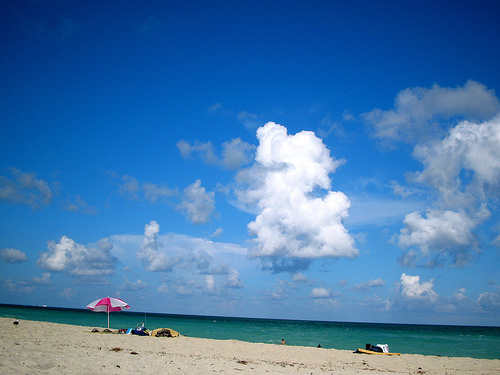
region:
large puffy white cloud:
[206, 75, 381, 278]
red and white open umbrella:
[61, 270, 166, 351]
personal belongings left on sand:
[116, 306, 201, 348]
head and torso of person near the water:
[255, 315, 301, 351]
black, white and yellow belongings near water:
[346, 320, 402, 360]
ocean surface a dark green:
[66, 297, 476, 357]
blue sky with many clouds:
[56, 76, 476, 281]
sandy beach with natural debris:
[35, 102, 445, 282]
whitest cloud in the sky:
[135, 85, 436, 280]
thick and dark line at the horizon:
[46, 297, 487, 344]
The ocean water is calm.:
[0, 297, 498, 367]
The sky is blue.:
[0, 0, 498, 117]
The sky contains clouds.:
[185, 111, 468, 279]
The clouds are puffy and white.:
[221, 111, 385, 286]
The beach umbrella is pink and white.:
[71, 288, 135, 338]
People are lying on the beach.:
[350, 337, 414, 361]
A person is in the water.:
[267, 330, 292, 350]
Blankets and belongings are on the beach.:
[87, 314, 191, 344]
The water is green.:
[0, 294, 497, 361]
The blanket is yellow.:
[350, 345, 407, 360]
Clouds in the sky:
[238, 111, 359, 273]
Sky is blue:
[1, 8, 498, 298]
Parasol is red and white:
[83, 286, 132, 336]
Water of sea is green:
[1, 291, 499, 338]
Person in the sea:
[272, 331, 296, 351]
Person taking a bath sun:
[128, 319, 157, 343]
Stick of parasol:
[102, 306, 114, 331]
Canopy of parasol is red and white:
[74, 294, 133, 318]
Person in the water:
[313, 339, 324, 352]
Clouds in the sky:
[35, 229, 118, 279]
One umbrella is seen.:
[85, 290, 135, 307]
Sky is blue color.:
[35, 125, 175, 195]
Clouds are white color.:
[270, 145, 310, 255]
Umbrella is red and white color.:
[85, 290, 115, 315]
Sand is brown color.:
[10, 331, 90, 361]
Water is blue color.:
[210, 311, 285, 331]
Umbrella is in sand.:
[70, 280, 120, 315]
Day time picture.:
[25, 40, 471, 365]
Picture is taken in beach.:
[25, 56, 482, 371]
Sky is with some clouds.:
[35, 42, 465, 305]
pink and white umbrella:
[86, 294, 128, 324]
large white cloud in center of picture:
[246, 118, 358, 268]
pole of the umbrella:
[104, 303, 114, 330]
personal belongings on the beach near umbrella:
[88, 320, 176, 336]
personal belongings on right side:
[354, 337, 400, 358]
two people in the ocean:
[275, 336, 327, 348]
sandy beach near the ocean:
[2, 320, 496, 373]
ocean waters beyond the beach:
[2, 292, 498, 358]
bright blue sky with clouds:
[0, 8, 498, 325]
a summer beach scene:
[0, 1, 498, 373]